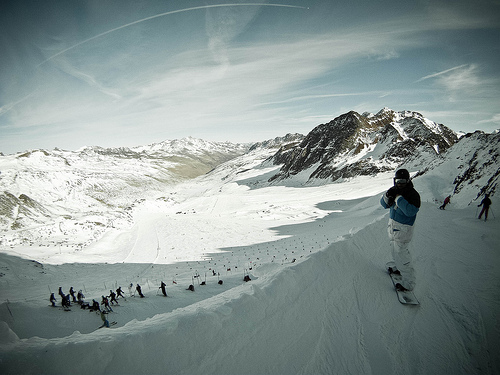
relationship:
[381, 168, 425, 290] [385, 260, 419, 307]
man on top of snowboard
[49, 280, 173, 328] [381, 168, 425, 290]
group to left of man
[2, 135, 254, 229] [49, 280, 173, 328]
mountain behind group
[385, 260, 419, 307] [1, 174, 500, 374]
snowboard on top of snow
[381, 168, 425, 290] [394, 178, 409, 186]
man wearing goggles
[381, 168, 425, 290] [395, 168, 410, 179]
man wearing helmet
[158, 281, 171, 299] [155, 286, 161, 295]
skier using ski pole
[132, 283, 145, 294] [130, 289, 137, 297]
skier using ski pole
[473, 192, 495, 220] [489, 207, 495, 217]
skier using ski pole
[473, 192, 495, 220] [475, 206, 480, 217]
skier using ski pole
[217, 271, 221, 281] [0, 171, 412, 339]
slalom flag located on ski slope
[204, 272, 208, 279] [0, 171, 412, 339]
slalom flag located on ski slope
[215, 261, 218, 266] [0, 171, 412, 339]
slalom flag located on ski slope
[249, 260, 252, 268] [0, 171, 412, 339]
slalom flag located on ski slope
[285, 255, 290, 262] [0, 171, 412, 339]
slalom flag located on ski slope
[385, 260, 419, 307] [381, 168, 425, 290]
snowboard under man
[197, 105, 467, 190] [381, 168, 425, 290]
mountain behind man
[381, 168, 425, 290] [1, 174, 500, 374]
man standing on snow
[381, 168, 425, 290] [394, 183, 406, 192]
man wearing mask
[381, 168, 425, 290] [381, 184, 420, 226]
man wearing jacket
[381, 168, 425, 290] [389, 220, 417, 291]
man wearing pants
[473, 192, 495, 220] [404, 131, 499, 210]
skier next to mountain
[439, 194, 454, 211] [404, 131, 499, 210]
skier next to mountain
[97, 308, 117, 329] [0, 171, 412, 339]
skier located on ski slope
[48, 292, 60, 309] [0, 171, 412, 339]
skier located on ski slope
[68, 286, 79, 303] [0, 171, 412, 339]
skier located on ski slope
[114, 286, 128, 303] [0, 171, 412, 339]
skier located on ski slope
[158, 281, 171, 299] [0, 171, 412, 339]
skier located on ski slope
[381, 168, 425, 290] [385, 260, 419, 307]
man riding snowboard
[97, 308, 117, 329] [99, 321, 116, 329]
skier wearing skis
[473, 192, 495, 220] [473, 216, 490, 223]
skier wearing skis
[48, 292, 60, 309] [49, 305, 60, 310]
skier wearing skis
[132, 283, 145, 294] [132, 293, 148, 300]
skier wearing skis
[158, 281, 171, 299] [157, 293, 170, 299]
skier wearing skis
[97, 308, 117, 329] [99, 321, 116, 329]
skier on top of skis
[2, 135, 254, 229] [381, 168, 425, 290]
mountain behind man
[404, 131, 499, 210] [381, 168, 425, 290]
mountain behind man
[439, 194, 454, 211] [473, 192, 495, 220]
skier to left of skier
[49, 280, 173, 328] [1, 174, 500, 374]
group skiing in snow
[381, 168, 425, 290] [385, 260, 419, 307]
man standing on snowboard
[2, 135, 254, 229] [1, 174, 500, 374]
mountain covered in snow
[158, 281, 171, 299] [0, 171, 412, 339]
skier skiing down ski slope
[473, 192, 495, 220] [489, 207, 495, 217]
skier holding ski pole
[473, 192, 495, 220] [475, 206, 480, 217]
skier holding ski pole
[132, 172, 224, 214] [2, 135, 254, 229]
valley next to mountain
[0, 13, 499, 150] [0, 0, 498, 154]
clouds floating in sky